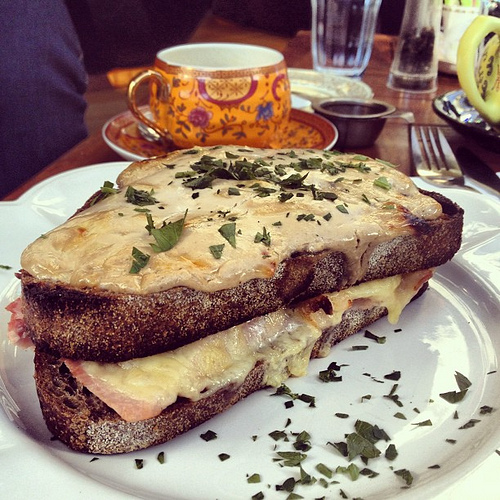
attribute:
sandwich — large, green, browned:
[23, 140, 465, 454]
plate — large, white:
[3, 249, 496, 499]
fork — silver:
[408, 123, 480, 196]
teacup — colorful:
[131, 43, 291, 153]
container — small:
[314, 98, 391, 148]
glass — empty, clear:
[307, 0, 382, 76]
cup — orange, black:
[129, 40, 291, 149]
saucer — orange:
[100, 101, 339, 163]